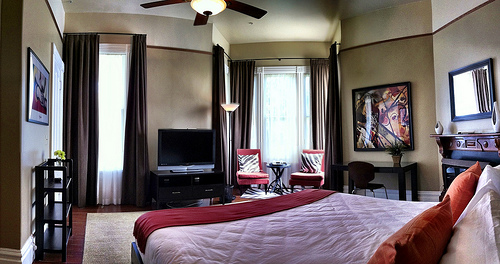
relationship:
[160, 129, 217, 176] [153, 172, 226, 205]
tv on table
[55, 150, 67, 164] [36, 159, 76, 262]
flower on bookstand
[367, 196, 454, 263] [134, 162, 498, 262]
pillow on bed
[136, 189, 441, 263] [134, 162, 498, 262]
comforter on bed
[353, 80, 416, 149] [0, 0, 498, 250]
painting on wall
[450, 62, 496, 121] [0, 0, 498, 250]
mirror on wall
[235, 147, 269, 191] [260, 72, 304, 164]
chair in front of window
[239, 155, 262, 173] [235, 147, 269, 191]
pillow on chair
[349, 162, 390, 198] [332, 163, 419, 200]
chair in front of desk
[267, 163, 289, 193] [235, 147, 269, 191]
table by chair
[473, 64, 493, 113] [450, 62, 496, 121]
curtain in mirror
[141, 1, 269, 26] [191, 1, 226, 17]
ceiling fan with light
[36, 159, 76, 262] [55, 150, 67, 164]
bookstand has flower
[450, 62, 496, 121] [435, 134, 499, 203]
mirror above fireplace mantel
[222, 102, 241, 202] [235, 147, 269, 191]
lamp behind chair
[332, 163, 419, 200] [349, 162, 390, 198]
desk with chair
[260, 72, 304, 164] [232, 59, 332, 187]
window with curtains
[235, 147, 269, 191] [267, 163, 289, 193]
chair by table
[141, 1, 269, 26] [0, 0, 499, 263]
ceiling fan in room